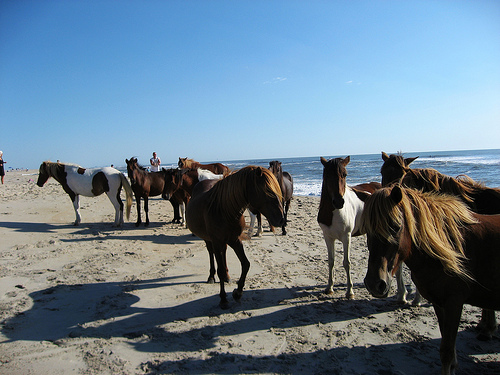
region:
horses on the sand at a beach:
[33, 155, 498, 314]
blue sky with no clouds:
[7, 9, 494, 133]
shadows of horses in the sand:
[2, 276, 208, 352]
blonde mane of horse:
[375, 184, 489, 245]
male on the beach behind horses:
[144, 149, 165, 174]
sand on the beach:
[9, 240, 135, 281]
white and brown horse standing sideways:
[32, 155, 134, 229]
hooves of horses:
[204, 279, 366, 311]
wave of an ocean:
[432, 149, 499, 174]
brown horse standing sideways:
[122, 156, 196, 225]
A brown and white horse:
[37, 161, 133, 224]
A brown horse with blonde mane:
[358, 187, 499, 369]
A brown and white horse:
[318, 155, 385, 301]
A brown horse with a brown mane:
[185, 166, 287, 308]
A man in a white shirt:
[148, 152, 160, 170]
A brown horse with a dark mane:
[126, 158, 190, 226]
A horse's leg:
[340, 236, 355, 300]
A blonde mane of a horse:
[360, 182, 476, 282]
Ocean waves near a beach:
[291, 180, 322, 198]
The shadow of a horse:
[3, 270, 198, 345]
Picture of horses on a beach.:
[13, 89, 498, 368]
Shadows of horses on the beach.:
[8, 265, 408, 370]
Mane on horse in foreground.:
[353, 181, 487, 280]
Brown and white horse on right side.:
[314, 153, 371, 306]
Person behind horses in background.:
[145, 147, 163, 173]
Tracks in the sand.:
[19, 232, 174, 284]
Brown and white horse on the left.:
[36, 157, 135, 226]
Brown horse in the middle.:
[183, 155, 288, 316]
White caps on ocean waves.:
[433, 152, 495, 177]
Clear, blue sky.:
[92, 30, 378, 124]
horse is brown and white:
[303, 123, 390, 329]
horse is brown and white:
[20, 154, 147, 221]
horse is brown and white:
[186, 134, 313, 216]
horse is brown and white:
[281, 153, 382, 276]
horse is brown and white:
[259, 158, 424, 312]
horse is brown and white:
[290, 143, 345, 293]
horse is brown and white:
[20, 122, 148, 265]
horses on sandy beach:
[33, 156, 488, 338]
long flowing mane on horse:
[412, 212, 467, 269]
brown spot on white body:
[86, 167, 113, 202]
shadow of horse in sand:
[8, 261, 188, 354]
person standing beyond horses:
[142, 146, 168, 173]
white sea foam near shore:
[295, 169, 317, 191]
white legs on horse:
[318, 233, 356, 302]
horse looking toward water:
[234, 160, 297, 244]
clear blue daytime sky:
[101, 44, 210, 116]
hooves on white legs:
[315, 282, 362, 303]